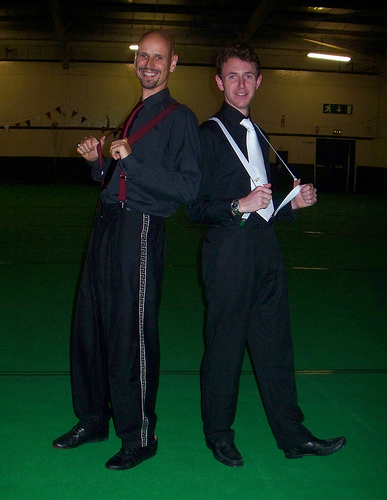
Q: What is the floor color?
A: Green.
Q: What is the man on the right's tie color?
A: White.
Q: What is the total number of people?
A: 2.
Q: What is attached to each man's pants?
A: Suspenders.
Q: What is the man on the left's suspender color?
A: Red.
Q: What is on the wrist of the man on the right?
A: Watch.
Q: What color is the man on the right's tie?
A: White.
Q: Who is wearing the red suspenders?
A: The man on the left.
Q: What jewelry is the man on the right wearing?
A: Wrist watch.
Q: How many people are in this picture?
A: Two.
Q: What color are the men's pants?
A: Black.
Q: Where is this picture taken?
A: In a gym.